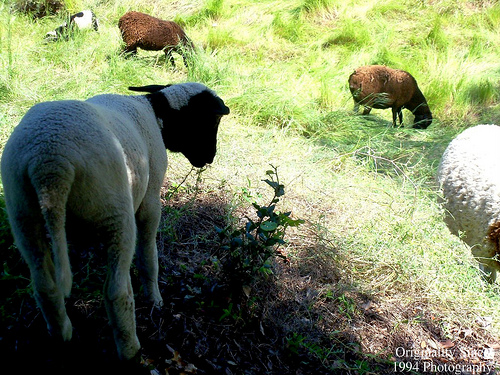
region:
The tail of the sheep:
[33, 169, 74, 292]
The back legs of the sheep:
[14, 214, 139, 355]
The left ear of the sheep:
[127, 81, 164, 93]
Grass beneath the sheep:
[1, 1, 496, 372]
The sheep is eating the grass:
[350, 68, 429, 128]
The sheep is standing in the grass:
[3, 82, 229, 358]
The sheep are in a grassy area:
[1, 9, 499, 361]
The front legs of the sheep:
[391, 106, 405, 128]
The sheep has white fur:
[441, 124, 498, 271]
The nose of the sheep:
[205, 150, 220, 165]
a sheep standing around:
[2, 82, 232, 353]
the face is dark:
[189, 90, 229, 167]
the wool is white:
[81, 112, 126, 159]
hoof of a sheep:
[117, 335, 141, 356]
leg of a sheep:
[136, 199, 164, 311]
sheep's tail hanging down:
[30, 158, 74, 295]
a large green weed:
[231, 165, 303, 277]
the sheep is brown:
[347, 65, 432, 129]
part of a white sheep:
[439, 121, 499, 278]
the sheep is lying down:
[47, 9, 95, 41]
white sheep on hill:
[51, 49, 242, 332]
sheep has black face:
[167, 86, 223, 166]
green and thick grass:
[255, 9, 352, 70]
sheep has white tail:
[21, 156, 77, 288]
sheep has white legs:
[42, 233, 189, 333]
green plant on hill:
[198, 152, 308, 305]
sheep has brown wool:
[331, 55, 431, 136]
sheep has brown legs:
[350, 96, 430, 123]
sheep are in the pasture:
[18, 11, 490, 366]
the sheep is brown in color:
[116, 5, 201, 65]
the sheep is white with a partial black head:
[0, 75, 231, 361]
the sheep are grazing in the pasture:
[38, 3, 434, 133]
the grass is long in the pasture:
[197, 11, 467, 165]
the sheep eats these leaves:
[176, 143, 223, 217]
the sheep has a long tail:
[26, 167, 95, 302]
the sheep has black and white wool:
[43, 7, 106, 54]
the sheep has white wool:
[426, 123, 496, 237]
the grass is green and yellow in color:
[275, 7, 460, 133]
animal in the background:
[10, 16, 497, 332]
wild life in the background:
[25, 8, 476, 340]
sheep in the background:
[44, 15, 498, 368]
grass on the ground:
[234, 11, 491, 124]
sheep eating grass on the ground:
[324, 26, 490, 193]